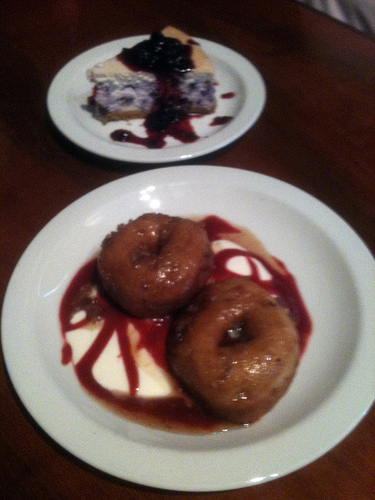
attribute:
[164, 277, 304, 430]
doughnuts — brown, round, cake, glazed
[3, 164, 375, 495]
plate — white, large, round, dessert, plain white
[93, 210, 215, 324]
doughnuts — brown, round, cake, glazed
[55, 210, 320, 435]
sauce — brown, red, thick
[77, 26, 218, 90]
dessert — white, creamy, sliced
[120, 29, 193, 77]
sauce — blue, blackbery, blackberry, raspberry, blueberry, droplets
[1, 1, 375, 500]
table — brown, wood, wooden, dark wood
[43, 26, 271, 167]
plate — small, white, dessert, round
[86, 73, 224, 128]
food — piece, blueberry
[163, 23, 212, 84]
crust — graham